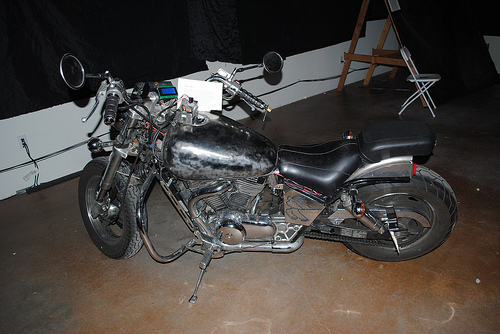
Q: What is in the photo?
A: A motorbike.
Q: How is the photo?
A: Clear.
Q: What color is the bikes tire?
A: Black.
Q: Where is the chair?
A: Next to the wood.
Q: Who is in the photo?
A: Nobody.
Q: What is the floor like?
A: Cement.